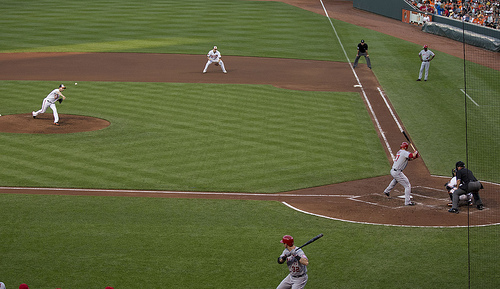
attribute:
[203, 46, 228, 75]
man — playing, ready, in stance, preparing, practicing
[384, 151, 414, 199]
uniform — red, white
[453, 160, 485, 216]
umpire — watching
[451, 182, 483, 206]
pants — grey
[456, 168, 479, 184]
shirt — black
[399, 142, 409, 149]
helmet — red, safety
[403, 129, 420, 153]
bat — black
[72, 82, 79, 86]
ball — flying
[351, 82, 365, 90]
base — white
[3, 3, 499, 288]
field. — grass, artificial, green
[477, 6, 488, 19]
people — watching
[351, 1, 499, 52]
stands — green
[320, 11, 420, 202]
line — white, long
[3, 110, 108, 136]
pitcher mound — circle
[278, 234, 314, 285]
man — practicing